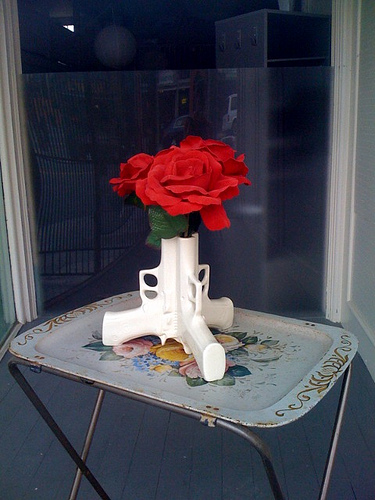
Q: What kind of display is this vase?
A: Artistic.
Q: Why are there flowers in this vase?
A: For decoration.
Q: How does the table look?
A: Dirty.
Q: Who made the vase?
A: An artist.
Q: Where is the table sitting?
A: On a porch.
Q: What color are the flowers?
A: Red.